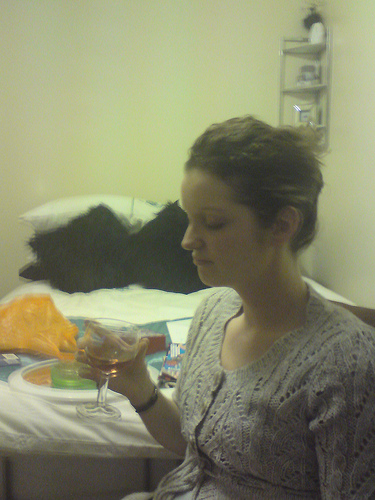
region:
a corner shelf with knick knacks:
[275, 4, 331, 157]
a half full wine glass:
[74, 317, 140, 424]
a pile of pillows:
[17, 193, 216, 295]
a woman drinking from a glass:
[70, 112, 373, 499]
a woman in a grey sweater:
[70, 114, 373, 499]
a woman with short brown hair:
[71, 114, 373, 499]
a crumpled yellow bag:
[0, 291, 85, 371]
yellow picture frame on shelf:
[291, 99, 319, 128]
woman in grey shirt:
[70, 116, 351, 488]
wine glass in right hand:
[61, 317, 155, 420]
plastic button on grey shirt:
[197, 397, 208, 415]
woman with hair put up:
[170, 108, 328, 297]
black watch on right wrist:
[131, 381, 164, 416]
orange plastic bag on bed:
[3, 292, 83, 367]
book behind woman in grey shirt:
[157, 338, 190, 388]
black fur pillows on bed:
[19, 201, 189, 298]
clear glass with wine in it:
[79, 312, 144, 424]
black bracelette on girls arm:
[137, 376, 161, 419]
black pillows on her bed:
[21, 206, 193, 305]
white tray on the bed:
[1, 358, 106, 404]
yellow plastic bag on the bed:
[6, 280, 78, 358]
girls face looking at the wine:
[178, 164, 261, 294]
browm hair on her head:
[193, 124, 330, 240]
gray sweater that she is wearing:
[166, 278, 373, 498]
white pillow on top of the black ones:
[20, 195, 167, 225]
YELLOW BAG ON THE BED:
[0, 292, 75, 355]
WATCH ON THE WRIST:
[138, 386, 156, 412]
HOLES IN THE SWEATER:
[273, 392, 288, 399]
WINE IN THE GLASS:
[86, 356, 118, 371]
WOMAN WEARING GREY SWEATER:
[266, 362, 317, 417]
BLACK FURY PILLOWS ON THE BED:
[55, 210, 134, 294]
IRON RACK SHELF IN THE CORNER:
[322, 108, 327, 148]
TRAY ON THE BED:
[36, 368, 45, 386]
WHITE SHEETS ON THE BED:
[128, 295, 159, 310]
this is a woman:
[11, 37, 361, 429]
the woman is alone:
[53, 106, 285, 384]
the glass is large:
[64, 304, 173, 406]